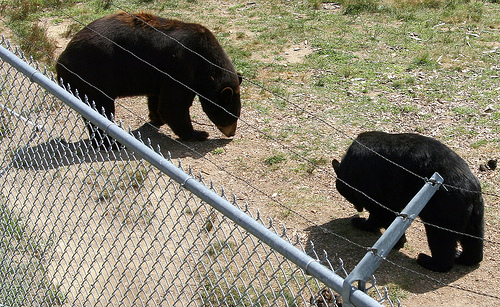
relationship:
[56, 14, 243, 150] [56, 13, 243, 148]
bear has fur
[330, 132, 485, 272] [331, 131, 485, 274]
bear has fur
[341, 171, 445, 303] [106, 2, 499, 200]
bracket for wire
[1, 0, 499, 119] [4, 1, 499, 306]
foliage on top of ground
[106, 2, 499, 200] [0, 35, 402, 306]
wire on top of fence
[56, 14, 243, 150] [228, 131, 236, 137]
bear has nose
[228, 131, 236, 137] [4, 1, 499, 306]
nose pointed to ground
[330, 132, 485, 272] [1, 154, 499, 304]
bear in middle of dirt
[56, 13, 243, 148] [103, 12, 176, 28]
fur has patch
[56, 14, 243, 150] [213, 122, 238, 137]
bear has snout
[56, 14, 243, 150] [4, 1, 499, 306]
bear sniffing ground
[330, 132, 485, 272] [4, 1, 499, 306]
bear sniffing ground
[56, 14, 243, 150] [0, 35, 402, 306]
bear behind fence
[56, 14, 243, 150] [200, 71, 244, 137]
bear has head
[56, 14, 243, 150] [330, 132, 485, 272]
bear next to bear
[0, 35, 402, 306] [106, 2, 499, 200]
fence has wire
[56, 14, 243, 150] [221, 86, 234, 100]
bear has ear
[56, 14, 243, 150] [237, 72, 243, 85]
bear has ear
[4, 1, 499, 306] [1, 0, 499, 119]
ground has foliage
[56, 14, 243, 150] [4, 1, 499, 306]
bear looking at ground